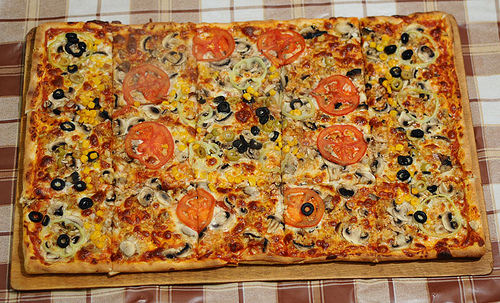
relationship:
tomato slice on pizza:
[250, 27, 313, 76] [13, 10, 483, 271]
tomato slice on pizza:
[306, 73, 364, 120] [13, 10, 483, 271]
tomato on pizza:
[317, 124, 369, 165] [13, 10, 483, 271]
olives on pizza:
[206, 85, 277, 155] [13, 10, 483, 271]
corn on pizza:
[75, 47, 120, 259] [13, 10, 483, 271]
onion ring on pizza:
[224, 56, 273, 96] [13, 10, 483, 271]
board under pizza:
[5, 13, 494, 291] [13, 10, 483, 271]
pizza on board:
[13, 10, 483, 271] [5, 13, 494, 291]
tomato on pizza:
[312, 121, 370, 170] [13, 10, 483, 271]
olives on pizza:
[49, 164, 94, 212] [13, 10, 483, 271]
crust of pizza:
[25, 246, 481, 268] [13, 10, 483, 271]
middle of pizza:
[212, 87, 296, 159] [13, 10, 483, 271]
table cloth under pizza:
[0, 0, 500, 303] [13, 10, 483, 271]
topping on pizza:
[217, 168, 243, 183] [13, 10, 483, 271]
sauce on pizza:
[439, 55, 453, 102] [13, 10, 483, 271]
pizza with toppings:
[13, 10, 483, 271] [38, 30, 437, 239]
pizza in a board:
[13, 10, 483, 271] [5, 13, 494, 291]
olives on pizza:
[379, 30, 415, 80] [13, 10, 483, 271]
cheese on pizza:
[292, 156, 315, 178] [13, 10, 483, 271]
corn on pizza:
[238, 80, 258, 107] [13, 10, 483, 271]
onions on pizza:
[44, 217, 85, 257] [13, 10, 483, 271]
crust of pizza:
[16, 21, 47, 257] [13, 10, 483, 271]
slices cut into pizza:
[109, 24, 125, 255] [13, 10, 483, 271]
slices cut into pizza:
[188, 27, 199, 250] [13, 10, 483, 271]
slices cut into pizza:
[280, 24, 286, 248] [13, 10, 483, 271]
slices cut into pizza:
[356, 21, 383, 247] [13, 10, 483, 271]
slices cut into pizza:
[45, 176, 464, 187] [13, 10, 483, 271]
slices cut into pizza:
[39, 98, 469, 107] [13, 10, 483, 271]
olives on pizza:
[391, 151, 413, 184] [13, 10, 483, 271]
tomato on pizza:
[125, 121, 175, 171] [13, 10, 483, 271]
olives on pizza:
[62, 30, 87, 73] [13, 10, 483, 271]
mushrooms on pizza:
[338, 220, 415, 251] [13, 10, 483, 271]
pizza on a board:
[13, 10, 483, 271] [5, 13, 494, 291]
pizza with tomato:
[13, 10, 483, 271] [314, 123, 365, 167]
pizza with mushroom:
[13, 10, 483, 271] [431, 206, 471, 238]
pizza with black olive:
[13, 10, 483, 271] [208, 85, 238, 124]